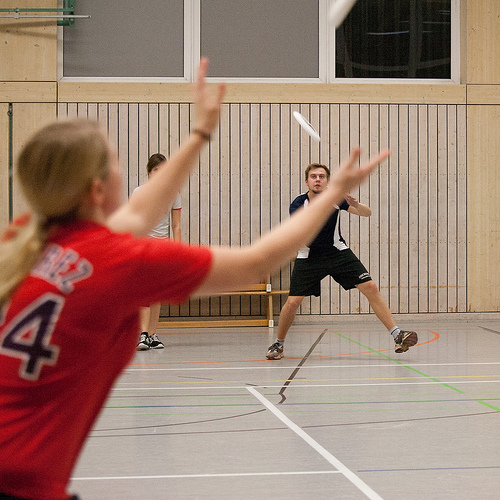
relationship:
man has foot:
[296, 156, 336, 199] [257, 316, 315, 364]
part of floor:
[290, 369, 373, 481] [351, 432, 384, 438]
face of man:
[313, 165, 334, 188] [296, 156, 336, 199]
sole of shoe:
[404, 329, 425, 350] [408, 326, 418, 351]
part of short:
[290, 369, 373, 481] [279, 247, 356, 303]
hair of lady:
[59, 188, 80, 195] [32, 92, 119, 303]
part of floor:
[290, 369, 373, 481] [0, 332, 499, 500]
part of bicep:
[356, 199, 378, 221] [346, 202, 375, 232]